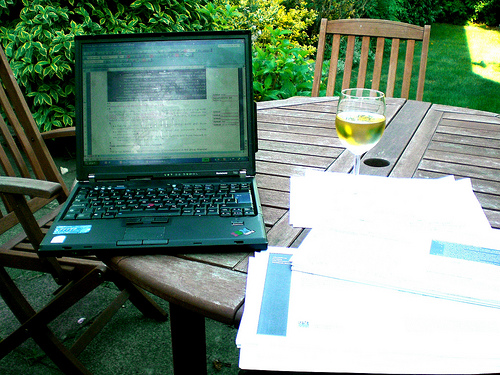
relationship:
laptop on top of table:
[38, 32, 267, 253] [99, 93, 496, 371]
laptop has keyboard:
[38, 32, 267, 253] [63, 184, 255, 224]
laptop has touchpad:
[38, 32, 267, 253] [117, 221, 167, 247]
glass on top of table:
[336, 90, 385, 175] [99, 93, 496, 371]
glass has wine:
[336, 90, 385, 175] [337, 113, 385, 151]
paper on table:
[236, 171, 499, 375] [99, 93, 496, 371]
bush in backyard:
[1, 0, 316, 132] [0, 1, 498, 371]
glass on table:
[336, 90, 385, 175] [99, 93, 496, 371]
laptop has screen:
[38, 32, 267, 253] [81, 39, 248, 165]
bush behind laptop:
[1, 0, 316, 132] [38, 32, 267, 253]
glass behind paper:
[336, 90, 385, 175] [236, 171, 499, 375]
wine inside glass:
[337, 113, 385, 151] [336, 90, 385, 175]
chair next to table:
[311, 17, 430, 100] [99, 93, 496, 371]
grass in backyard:
[325, 25, 500, 112] [0, 1, 498, 371]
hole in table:
[364, 158, 390, 169] [99, 93, 496, 371]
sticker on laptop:
[52, 235, 66, 244] [38, 32, 267, 253]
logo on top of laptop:
[231, 226, 253, 238] [38, 32, 267, 253]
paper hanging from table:
[236, 171, 499, 375] [99, 93, 496, 371]